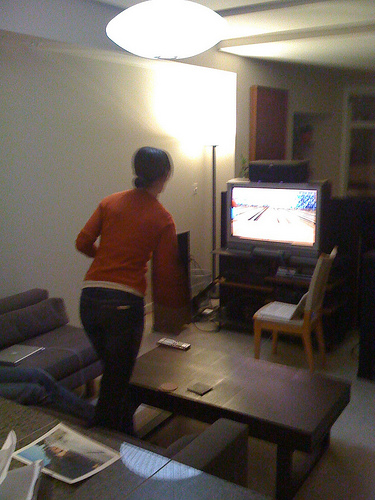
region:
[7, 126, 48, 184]
part of a wall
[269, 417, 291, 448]
edge of a table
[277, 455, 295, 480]
part of a stand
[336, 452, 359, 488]
part of a shhade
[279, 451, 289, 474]
part fo a stand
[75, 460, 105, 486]
edge of a picture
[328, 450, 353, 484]
part of a floor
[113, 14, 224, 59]
the light is on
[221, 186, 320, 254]
the television is switched on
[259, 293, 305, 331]
a laptop is placed on the chair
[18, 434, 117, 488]
a photo is on the seat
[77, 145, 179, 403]
a lady is standing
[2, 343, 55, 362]
a laptop is switched off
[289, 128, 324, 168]
someone is standing on the door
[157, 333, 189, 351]
a remote control is on the table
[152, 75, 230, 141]
light is reflected on the board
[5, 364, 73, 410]
the legs are folded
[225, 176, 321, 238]
this is a television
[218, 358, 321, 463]
this is a table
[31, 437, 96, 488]
this is a magazine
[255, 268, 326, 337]
this is a chair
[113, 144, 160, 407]
this is a lady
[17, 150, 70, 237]
this is the wall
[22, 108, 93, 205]
the wall is white in color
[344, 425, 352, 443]
this is the floor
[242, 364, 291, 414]
the table is wooden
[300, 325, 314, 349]
the chair is brown in color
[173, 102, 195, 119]
part of a chart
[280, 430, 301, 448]
edge of a table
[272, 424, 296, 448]
part of a table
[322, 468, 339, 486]
part of a floor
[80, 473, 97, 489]
edge of a paper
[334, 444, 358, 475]
part of a shade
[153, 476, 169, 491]
part of a shade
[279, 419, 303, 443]
part of a table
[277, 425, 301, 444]
edge fo a table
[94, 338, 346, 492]
A wooden coffee table.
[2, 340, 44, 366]
A silver laptop.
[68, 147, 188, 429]
A woman playing the wii.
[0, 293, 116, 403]
A grey sofa.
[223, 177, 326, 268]
A silver framed television.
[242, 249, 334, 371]
A wooden chair.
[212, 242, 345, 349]
An entertainment stand.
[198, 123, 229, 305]
A lit up floor lamp.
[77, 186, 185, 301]
A long sleeved orange shirt.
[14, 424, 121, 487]
A picture on the counter.